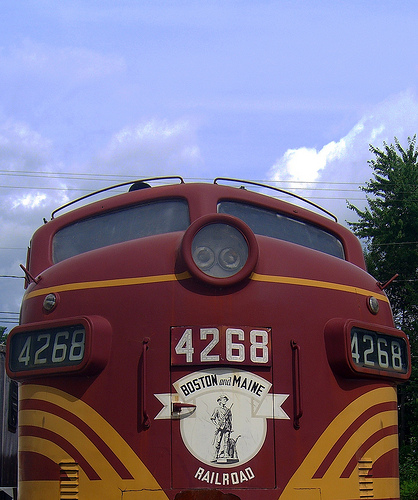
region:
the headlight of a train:
[190, 220, 250, 275]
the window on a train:
[45, 192, 187, 262]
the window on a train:
[220, 197, 348, 257]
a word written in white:
[191, 462, 254, 487]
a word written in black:
[180, 372, 216, 392]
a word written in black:
[229, 369, 268, 401]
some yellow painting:
[17, 385, 147, 499]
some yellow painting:
[283, 387, 401, 495]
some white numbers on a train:
[174, 321, 268, 366]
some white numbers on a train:
[8, 324, 88, 362]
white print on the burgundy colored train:
[170, 327, 270, 364]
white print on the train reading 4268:
[171, 326, 272, 364]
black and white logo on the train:
[153, 363, 292, 487]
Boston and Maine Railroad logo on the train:
[153, 365, 292, 486]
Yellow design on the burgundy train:
[309, 386, 397, 498]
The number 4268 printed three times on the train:
[9, 326, 402, 374]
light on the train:
[35, 292, 66, 316]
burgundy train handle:
[290, 338, 304, 437]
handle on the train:
[173, 401, 197, 414]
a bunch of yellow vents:
[57, 459, 80, 499]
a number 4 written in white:
[16, 335, 34, 367]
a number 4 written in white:
[171, 322, 196, 362]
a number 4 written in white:
[348, 324, 362, 364]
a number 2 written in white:
[31, 330, 50, 365]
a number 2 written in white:
[196, 327, 220, 366]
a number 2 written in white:
[359, 331, 377, 365]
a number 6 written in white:
[49, 327, 69, 358]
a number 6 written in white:
[223, 324, 248, 362]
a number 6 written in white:
[375, 333, 386, 371]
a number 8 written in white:
[248, 326, 270, 365]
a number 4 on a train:
[15, 336, 36, 365]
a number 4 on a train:
[347, 328, 361, 364]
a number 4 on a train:
[172, 326, 200, 370]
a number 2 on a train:
[197, 325, 220, 362]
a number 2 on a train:
[30, 330, 52, 365]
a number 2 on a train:
[360, 334, 376, 365]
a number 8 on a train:
[249, 329, 268, 362]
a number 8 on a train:
[66, 330, 85, 362]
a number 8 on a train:
[389, 339, 405, 371]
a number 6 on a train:
[225, 326, 246, 366]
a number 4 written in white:
[14, 331, 30, 366]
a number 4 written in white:
[175, 318, 190, 364]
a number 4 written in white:
[346, 325, 357, 363]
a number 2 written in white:
[30, 332, 50, 361]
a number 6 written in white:
[51, 330, 65, 364]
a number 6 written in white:
[225, 326, 244, 360]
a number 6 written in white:
[375, 335, 388, 366]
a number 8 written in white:
[387, 337, 403, 371]